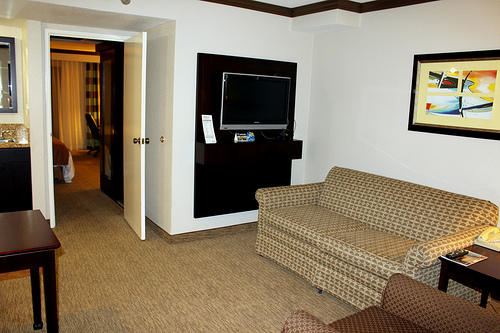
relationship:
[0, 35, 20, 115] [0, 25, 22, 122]
mirror hanging on wall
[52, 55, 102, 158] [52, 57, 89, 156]
window closed curtains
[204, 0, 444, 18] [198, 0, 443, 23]
trim hanging ceiling